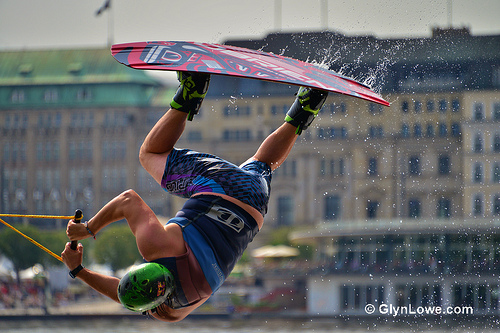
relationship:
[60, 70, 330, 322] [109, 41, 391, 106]
man on board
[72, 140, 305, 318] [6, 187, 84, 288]
man holding rope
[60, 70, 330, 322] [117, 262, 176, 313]
man with green helmet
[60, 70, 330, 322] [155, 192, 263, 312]
man wearing life vest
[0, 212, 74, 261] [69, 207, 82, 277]
rope with handle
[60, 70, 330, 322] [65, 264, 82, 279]
man wearing watch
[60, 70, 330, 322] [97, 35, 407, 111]
man on board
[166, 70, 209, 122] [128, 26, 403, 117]
boots on wake board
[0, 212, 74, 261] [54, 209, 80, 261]
rope on handle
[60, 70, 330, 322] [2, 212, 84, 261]
man on rope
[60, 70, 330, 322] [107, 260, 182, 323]
man on helmet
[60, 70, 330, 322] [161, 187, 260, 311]
man on tank top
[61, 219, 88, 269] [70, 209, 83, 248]
hands on handle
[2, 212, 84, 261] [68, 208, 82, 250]
rope on handle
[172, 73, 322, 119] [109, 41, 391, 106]
feet on board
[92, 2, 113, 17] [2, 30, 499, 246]
flag on building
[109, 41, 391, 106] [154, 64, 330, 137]
board on boots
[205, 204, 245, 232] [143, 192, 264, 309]
logo on life vest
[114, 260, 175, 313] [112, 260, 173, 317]
green helmet on head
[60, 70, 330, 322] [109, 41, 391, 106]
man on a board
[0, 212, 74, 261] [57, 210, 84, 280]
rope on a handle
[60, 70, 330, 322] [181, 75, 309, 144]
man has feet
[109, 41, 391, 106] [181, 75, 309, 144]
board on feet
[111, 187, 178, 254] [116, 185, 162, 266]
muscles are on bicep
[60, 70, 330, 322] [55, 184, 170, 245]
man has arm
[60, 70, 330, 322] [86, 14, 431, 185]
man has lower half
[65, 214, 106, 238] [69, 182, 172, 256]
bracelet has arm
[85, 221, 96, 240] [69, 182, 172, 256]
bracelet has arm